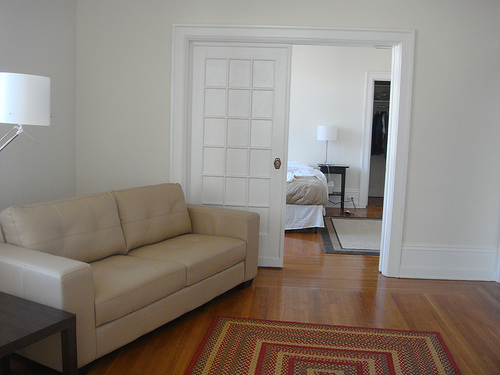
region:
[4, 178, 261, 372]
Beige leather two cushion sofa with loose back pillows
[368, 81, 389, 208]
Clothes hanging in the corner of a closet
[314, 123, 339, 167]
Table lamp with a silver base and white shade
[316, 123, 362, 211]
Wood table with a lamp on it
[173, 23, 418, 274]
White door with multiple panes and a gold tone handle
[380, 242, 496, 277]
Wide white baseboard molding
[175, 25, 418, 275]
Double door bedroom entryway with on door open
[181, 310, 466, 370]
Part of a red, brown and beige area rug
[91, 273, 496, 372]
Polished hardwood floor with an area rug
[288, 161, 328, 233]
Bed with beige comforter and white sheets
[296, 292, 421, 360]
a rug on the floor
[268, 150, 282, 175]
a doorknob on a door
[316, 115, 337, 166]
a lamp on a table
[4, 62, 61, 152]
a lmap over the couch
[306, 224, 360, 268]
a rug on the bedroom floor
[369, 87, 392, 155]
clothes in the closet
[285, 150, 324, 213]
sheets on the bed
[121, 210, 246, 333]
a couch in the living room area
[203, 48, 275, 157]
windows on the door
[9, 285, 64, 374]
a table next to the couch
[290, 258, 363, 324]
Medium brown hard wood floors.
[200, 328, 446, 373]
Multi colored rug on the floor.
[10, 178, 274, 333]
Beige couch in the living room.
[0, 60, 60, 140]
Creamy white lamp shade.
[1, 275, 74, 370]
Brown table beside the couch.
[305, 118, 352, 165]
Tall lamp on the table.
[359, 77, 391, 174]
Clothes in the closet.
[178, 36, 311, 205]
Door leading to the bedroom.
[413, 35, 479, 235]
Freshly painted white wall.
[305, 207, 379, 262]
Rug beside the bed.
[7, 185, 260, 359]
tan, leather couch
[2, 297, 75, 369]
brown end table by the couch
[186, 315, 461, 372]
red area rug in front of the couch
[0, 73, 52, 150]
white lamp over the couch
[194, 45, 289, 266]
white door to the bedroom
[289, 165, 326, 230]
a bed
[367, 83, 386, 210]
a closet in the bedroom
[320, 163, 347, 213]
brown end table by the bed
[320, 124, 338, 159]
lamp on bedroom end table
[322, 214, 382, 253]
tan and brown rug in bedroom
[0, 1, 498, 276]
white wall of room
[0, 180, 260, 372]
tan leather couch sitting diagonally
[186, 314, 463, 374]
red border around rug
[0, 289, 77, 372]
corner of wood table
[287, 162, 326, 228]
edge of unmade bed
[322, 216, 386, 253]
rug on wood floor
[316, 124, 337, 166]
white shade on lamp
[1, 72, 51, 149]
white shade on lamp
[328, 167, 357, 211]
electric plugs in wall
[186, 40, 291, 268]
white door with panels